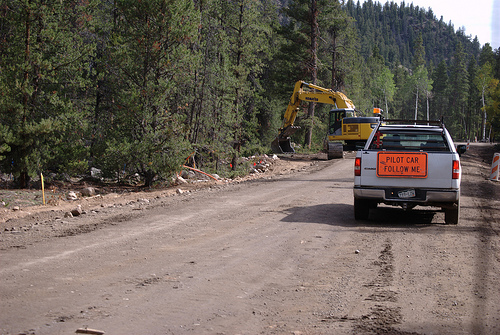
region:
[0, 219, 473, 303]
a road under construction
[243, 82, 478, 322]
a white pick up truck on a dirt road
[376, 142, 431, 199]
a orange and black sign on the back of a truck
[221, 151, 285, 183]
small orange flags stuck in the ground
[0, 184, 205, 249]
several rocks next to a road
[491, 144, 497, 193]
a orange and white barrel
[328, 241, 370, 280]
a rock in the middle of a road way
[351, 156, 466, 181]
red tail lights on a truck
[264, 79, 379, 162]
a large piece of machinery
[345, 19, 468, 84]
a hillside covered with trees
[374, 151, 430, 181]
Pilot car traffic control sign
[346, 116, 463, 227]
Pilot car used for road construction traverse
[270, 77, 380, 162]
Construction digger used to move dirt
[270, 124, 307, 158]
Metal bucket of construction digger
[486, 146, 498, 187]
Orange and white caution sign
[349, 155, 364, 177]
Illuminated tail light on vehicle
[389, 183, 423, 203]
Bent license plate on vehicle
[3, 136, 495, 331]
Road under construction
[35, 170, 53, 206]
Construction line boundary marker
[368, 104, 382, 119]
Flashing warning light on vehicle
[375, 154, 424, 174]
The orange sign says pilot car follow me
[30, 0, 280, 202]
There is a large forest along the road.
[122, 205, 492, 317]
The road is not paved.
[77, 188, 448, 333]
The road is leveled.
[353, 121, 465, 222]
The white truck is on the road.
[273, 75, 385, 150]
The construction crane is orange.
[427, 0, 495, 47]
It is daytime outside.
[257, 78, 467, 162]
The crane is on the left side of the road.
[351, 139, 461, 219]
The truck's break lights are on.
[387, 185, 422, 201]
The truck's license plate is in poor condition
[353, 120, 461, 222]
white truck on road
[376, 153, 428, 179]
orange sign on truck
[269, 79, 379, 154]
yellow construction truck on road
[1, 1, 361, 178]
trees with green leaves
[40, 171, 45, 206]
yellow pole in ground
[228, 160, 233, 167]
red reflector in ground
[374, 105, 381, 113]
yellow light on truck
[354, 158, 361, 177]
break light on truck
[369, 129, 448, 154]
rear window on truck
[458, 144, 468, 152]
black side mirror on truck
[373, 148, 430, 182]
orange and black sign on the back of a truck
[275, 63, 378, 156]
yellow contruction equipment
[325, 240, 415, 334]
tire tracks on a dirt road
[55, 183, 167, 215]
rocks alonside the road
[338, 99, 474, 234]
back of a white truck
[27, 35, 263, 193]
row of trees lining the street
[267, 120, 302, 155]
bucket on a digger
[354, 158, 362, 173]
red tail light of a truck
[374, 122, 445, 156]
back window of a truck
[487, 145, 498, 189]
white and orange traffic barrier